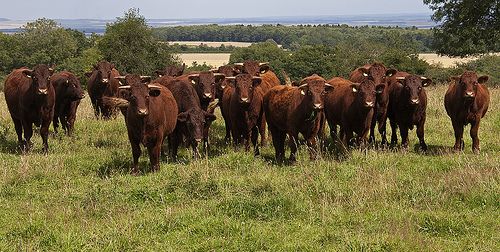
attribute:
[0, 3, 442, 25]
sky — gray, overcast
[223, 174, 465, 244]
grass — green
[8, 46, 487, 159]
cows — brown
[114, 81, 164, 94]
horns — sharp, pointed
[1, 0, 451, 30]
sky — blue, gray, hazy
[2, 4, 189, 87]
trees — large, wide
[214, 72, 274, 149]
cattle — brown, hairly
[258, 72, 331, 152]
cattle — hairly, brown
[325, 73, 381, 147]
cattle — hairly, brown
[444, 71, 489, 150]
cattle — hairly, brown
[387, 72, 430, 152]
cattle — hairly, brown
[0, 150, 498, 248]
grass — tall, green, uncut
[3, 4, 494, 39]
sun — shining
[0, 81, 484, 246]
field — grassy